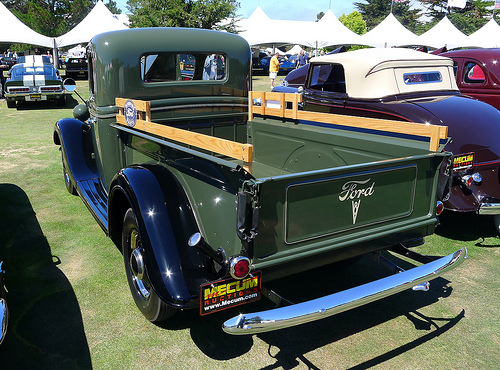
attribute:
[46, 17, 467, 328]
truck — green, big, wide, parked, wooden, shiny, dark green, dark, old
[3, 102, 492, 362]
grass — tiny, short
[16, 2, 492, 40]
sky — blue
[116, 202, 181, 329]
wheel — round, big, black